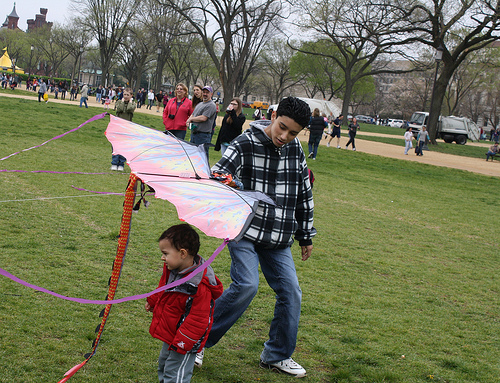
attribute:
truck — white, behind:
[408, 108, 468, 146]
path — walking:
[282, 120, 495, 182]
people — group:
[163, 82, 248, 160]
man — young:
[148, 222, 215, 382]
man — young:
[195, 99, 318, 374]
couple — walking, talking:
[400, 121, 431, 161]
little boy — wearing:
[138, 222, 224, 381]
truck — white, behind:
[398, 99, 483, 152]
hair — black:
[263, 93, 313, 150]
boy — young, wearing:
[144, 220, 221, 382]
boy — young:
[144, 255, 224, 352]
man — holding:
[208, 95, 315, 380]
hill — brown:
[3, 19, 147, 137]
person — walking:
[414, 124, 431, 156]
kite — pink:
[4, 104, 279, 310]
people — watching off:
[51, 72, 173, 109]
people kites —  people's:
[102, 73, 266, 260]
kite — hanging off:
[28, 60, 324, 307]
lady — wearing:
[214, 96, 245, 151]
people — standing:
[191, 81, 212, 146]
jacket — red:
[144, 253, 229, 355]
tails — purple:
[5, 91, 227, 331]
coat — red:
[141, 257, 226, 357]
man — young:
[212, 91, 340, 377]